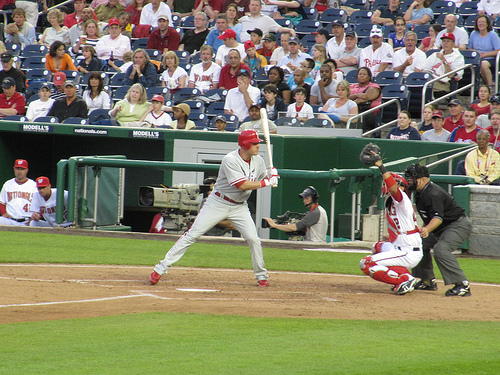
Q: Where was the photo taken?
A: It was taken at the stadium.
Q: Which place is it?
A: It is a stadium.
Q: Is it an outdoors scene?
A: Yes, it is outdoors.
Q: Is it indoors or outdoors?
A: It is outdoors.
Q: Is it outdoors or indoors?
A: It is outdoors.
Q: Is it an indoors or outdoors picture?
A: It is outdoors.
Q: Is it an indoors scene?
A: No, it is outdoors.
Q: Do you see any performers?
A: No, there are no performers.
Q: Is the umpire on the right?
A: Yes, the umpire is on the right of the image.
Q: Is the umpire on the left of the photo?
A: No, the umpire is on the right of the image.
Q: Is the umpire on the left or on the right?
A: The umpire is on the right of the image.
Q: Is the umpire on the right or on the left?
A: The umpire is on the right of the image.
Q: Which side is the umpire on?
A: The umpire is on the right of the image.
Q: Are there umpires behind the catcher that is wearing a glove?
A: Yes, there is an umpire behind the catcher.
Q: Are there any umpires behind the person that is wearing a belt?
A: Yes, there is an umpire behind the catcher.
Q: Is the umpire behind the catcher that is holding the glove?
A: Yes, the umpire is behind the catcher.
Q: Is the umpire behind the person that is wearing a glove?
A: Yes, the umpire is behind the catcher.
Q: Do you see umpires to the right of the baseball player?
A: Yes, there is an umpire to the right of the player.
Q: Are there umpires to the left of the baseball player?
A: No, the umpire is to the right of the player.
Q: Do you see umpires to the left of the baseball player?
A: No, the umpire is to the right of the player.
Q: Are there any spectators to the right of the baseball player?
A: No, there is an umpire to the right of the player.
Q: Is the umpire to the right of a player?
A: Yes, the umpire is to the right of a player.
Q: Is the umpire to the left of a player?
A: No, the umpire is to the right of a player.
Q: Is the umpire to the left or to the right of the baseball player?
A: The umpire is to the right of the player.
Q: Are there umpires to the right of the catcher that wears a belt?
A: Yes, there is an umpire to the right of the catcher.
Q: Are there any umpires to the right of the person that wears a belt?
A: Yes, there is an umpire to the right of the catcher.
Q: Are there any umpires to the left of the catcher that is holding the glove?
A: No, the umpire is to the right of the catcher.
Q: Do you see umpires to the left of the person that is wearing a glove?
A: No, the umpire is to the right of the catcher.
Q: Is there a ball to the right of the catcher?
A: No, there is an umpire to the right of the catcher.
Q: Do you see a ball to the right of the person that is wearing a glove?
A: No, there is an umpire to the right of the catcher.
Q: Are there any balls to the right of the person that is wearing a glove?
A: No, there is an umpire to the right of the catcher.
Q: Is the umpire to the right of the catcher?
A: Yes, the umpire is to the right of the catcher.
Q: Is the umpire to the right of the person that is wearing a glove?
A: Yes, the umpire is to the right of the catcher.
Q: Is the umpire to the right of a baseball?
A: No, the umpire is to the right of the catcher.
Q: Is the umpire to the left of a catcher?
A: No, the umpire is to the right of a catcher.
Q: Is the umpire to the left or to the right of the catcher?
A: The umpire is to the right of the catcher.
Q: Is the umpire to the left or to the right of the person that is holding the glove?
A: The umpire is to the right of the catcher.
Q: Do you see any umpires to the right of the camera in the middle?
A: Yes, there is an umpire to the right of the camera.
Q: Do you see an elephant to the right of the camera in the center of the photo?
A: No, there is an umpire to the right of the camera.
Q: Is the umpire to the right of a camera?
A: Yes, the umpire is to the right of a camera.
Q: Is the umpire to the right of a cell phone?
A: No, the umpire is to the right of a camera.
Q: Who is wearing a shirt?
A: The umpire is wearing a shirt.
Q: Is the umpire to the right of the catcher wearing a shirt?
A: Yes, the umpire is wearing a shirt.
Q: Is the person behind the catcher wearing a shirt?
A: Yes, the umpire is wearing a shirt.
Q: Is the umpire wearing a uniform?
A: No, the umpire is wearing a shirt.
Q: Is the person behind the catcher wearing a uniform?
A: No, the umpire is wearing a shirt.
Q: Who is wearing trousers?
A: The umpire is wearing trousers.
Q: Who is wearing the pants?
A: The umpire is wearing trousers.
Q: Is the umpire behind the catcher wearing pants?
A: Yes, the umpire is wearing pants.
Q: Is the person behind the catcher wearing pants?
A: Yes, the umpire is wearing pants.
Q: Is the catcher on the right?
A: Yes, the catcher is on the right of the image.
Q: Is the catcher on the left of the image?
A: No, the catcher is on the right of the image.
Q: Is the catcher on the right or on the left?
A: The catcher is on the right of the image.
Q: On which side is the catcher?
A: The catcher is on the right of the image.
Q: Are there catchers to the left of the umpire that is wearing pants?
A: Yes, there is a catcher to the left of the umpire.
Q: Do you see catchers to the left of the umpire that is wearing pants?
A: Yes, there is a catcher to the left of the umpire.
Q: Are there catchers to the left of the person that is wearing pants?
A: Yes, there is a catcher to the left of the umpire.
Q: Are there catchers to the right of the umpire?
A: No, the catcher is to the left of the umpire.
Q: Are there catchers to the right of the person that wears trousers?
A: No, the catcher is to the left of the umpire.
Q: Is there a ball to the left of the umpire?
A: No, there is a catcher to the left of the umpire.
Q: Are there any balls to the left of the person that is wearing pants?
A: No, there is a catcher to the left of the umpire.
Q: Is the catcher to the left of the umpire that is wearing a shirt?
A: Yes, the catcher is to the left of the umpire.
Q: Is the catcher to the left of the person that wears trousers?
A: Yes, the catcher is to the left of the umpire.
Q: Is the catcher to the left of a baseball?
A: No, the catcher is to the left of the umpire.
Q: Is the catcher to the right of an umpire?
A: No, the catcher is to the left of an umpire.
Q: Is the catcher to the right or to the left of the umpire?
A: The catcher is to the left of the umpire.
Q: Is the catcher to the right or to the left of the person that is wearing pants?
A: The catcher is to the left of the umpire.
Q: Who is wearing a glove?
A: The catcher is wearing a glove.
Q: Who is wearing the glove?
A: The catcher is wearing a glove.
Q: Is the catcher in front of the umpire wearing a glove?
A: Yes, the catcher is wearing a glove.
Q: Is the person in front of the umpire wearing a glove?
A: Yes, the catcher is wearing a glove.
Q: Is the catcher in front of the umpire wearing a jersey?
A: No, the catcher is wearing a glove.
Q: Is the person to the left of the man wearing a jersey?
A: No, the catcher is wearing a glove.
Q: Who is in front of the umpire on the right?
A: The catcher is in front of the umpire.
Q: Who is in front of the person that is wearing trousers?
A: The catcher is in front of the umpire.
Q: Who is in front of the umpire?
A: The catcher is in front of the umpire.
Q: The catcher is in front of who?
A: The catcher is in front of the umpire.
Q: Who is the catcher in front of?
A: The catcher is in front of the umpire.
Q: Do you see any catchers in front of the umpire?
A: Yes, there is a catcher in front of the umpire.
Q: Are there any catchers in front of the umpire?
A: Yes, there is a catcher in front of the umpire.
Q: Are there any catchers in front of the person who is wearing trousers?
A: Yes, there is a catcher in front of the umpire.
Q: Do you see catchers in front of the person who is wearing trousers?
A: Yes, there is a catcher in front of the umpire.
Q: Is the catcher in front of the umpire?
A: Yes, the catcher is in front of the umpire.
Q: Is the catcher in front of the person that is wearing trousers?
A: Yes, the catcher is in front of the umpire.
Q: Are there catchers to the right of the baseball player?
A: Yes, there is a catcher to the right of the player.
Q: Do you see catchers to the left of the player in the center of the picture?
A: No, the catcher is to the right of the player.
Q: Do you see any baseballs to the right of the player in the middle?
A: No, there is a catcher to the right of the player.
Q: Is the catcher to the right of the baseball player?
A: Yes, the catcher is to the right of the player.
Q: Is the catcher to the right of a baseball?
A: No, the catcher is to the right of the player.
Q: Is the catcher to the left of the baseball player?
A: No, the catcher is to the right of the player.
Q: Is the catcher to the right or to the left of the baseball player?
A: The catcher is to the right of the player.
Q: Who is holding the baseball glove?
A: The catcher is holding the glove.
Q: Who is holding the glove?
A: The catcher is holding the glove.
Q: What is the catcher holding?
A: The catcher is holding the glove.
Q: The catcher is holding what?
A: The catcher is holding the glove.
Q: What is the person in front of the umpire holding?
A: The catcher is holding the glove.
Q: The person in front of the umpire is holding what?
A: The catcher is holding the glove.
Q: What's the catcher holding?
A: The catcher is holding the glove.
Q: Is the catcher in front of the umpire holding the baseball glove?
A: Yes, the catcher is holding the glove.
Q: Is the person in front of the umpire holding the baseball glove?
A: Yes, the catcher is holding the glove.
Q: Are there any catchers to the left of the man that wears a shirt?
A: Yes, there is a catcher to the left of the man.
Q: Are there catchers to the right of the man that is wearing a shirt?
A: No, the catcher is to the left of the man.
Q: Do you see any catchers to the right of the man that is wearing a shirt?
A: No, the catcher is to the left of the man.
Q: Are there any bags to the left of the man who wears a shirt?
A: No, there is a catcher to the left of the man.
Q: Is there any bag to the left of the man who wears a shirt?
A: No, there is a catcher to the left of the man.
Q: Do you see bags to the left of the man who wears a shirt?
A: No, there is a catcher to the left of the man.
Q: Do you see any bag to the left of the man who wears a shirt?
A: No, there is a catcher to the left of the man.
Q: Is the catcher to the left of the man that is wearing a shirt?
A: Yes, the catcher is to the left of the man.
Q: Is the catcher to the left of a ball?
A: No, the catcher is to the left of the man.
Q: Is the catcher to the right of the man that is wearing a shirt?
A: No, the catcher is to the left of the man.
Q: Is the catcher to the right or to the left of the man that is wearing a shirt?
A: The catcher is to the left of the man.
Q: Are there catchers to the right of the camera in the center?
A: Yes, there is a catcher to the right of the camera.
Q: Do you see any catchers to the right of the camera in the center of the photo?
A: Yes, there is a catcher to the right of the camera.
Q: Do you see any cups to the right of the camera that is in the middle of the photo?
A: No, there is a catcher to the right of the camera.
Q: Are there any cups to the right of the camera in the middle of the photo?
A: No, there is a catcher to the right of the camera.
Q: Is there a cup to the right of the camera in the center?
A: No, there is a catcher to the right of the camera.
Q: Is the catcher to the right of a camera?
A: Yes, the catcher is to the right of a camera.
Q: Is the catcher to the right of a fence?
A: No, the catcher is to the right of a camera.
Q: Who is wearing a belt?
A: The catcher is wearing a belt.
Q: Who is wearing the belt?
A: The catcher is wearing a belt.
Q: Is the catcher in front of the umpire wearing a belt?
A: Yes, the catcher is wearing a belt.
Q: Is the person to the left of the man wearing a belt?
A: Yes, the catcher is wearing a belt.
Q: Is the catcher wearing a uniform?
A: No, the catcher is wearing a belt.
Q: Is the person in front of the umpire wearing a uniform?
A: No, the catcher is wearing a belt.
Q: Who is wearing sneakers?
A: The catcher is wearing sneakers.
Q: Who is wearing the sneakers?
A: The catcher is wearing sneakers.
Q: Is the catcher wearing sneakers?
A: Yes, the catcher is wearing sneakers.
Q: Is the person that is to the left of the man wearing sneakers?
A: Yes, the catcher is wearing sneakers.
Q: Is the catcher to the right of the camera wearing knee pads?
A: No, the catcher is wearing sneakers.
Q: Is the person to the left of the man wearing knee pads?
A: No, the catcher is wearing sneakers.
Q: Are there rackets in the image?
A: No, there are no rackets.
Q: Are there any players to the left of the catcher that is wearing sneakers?
A: Yes, there is a player to the left of the catcher.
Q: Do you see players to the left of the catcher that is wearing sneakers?
A: Yes, there is a player to the left of the catcher.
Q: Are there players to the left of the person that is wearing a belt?
A: Yes, there is a player to the left of the catcher.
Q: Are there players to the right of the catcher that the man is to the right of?
A: No, the player is to the left of the catcher.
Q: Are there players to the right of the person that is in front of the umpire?
A: No, the player is to the left of the catcher.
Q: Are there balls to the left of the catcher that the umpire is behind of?
A: No, there is a player to the left of the catcher.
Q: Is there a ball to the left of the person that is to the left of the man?
A: No, there is a player to the left of the catcher.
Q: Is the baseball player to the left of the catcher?
A: Yes, the player is to the left of the catcher.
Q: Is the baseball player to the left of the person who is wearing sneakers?
A: Yes, the player is to the left of the catcher.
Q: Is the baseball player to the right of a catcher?
A: No, the player is to the left of a catcher.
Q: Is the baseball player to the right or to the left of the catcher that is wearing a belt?
A: The player is to the left of the catcher.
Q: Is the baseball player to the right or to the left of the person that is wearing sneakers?
A: The player is to the left of the catcher.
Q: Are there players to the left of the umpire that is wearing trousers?
A: Yes, there is a player to the left of the umpire.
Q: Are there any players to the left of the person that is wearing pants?
A: Yes, there is a player to the left of the umpire.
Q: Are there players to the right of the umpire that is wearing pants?
A: No, the player is to the left of the umpire.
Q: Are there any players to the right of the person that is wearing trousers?
A: No, the player is to the left of the umpire.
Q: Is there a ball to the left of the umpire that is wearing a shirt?
A: No, there is a player to the left of the umpire.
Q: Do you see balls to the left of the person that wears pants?
A: No, there is a player to the left of the umpire.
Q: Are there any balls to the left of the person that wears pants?
A: No, there is a player to the left of the umpire.